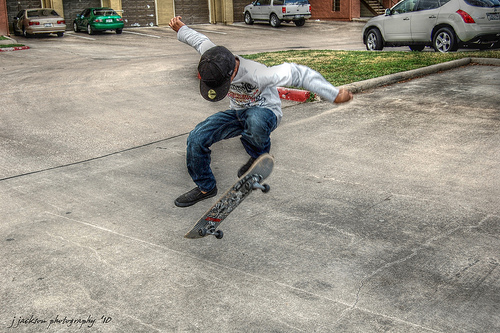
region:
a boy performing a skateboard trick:
[146, 16, 348, 260]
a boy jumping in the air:
[156, 36, 321, 268]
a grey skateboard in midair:
[183, 158, 277, 255]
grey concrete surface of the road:
[310, 188, 416, 265]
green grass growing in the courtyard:
[326, 53, 367, 71]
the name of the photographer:
[2, 311, 124, 331]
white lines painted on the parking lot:
[137, 29, 162, 42]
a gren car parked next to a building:
[73, 5, 145, 35]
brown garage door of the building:
[133, 0, 156, 23]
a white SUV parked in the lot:
[354, 2, 497, 53]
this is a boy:
[130, 32, 310, 210]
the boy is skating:
[151, 44, 311, 209]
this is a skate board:
[205, 170, 270, 237]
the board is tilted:
[204, 171, 258, 230]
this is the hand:
[285, 51, 352, 110]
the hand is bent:
[283, 61, 345, 109]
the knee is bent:
[242, 109, 277, 141]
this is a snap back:
[200, 52, 233, 94]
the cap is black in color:
[198, 52, 225, 78]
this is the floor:
[293, 217, 385, 327]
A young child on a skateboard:
[170, 21, 352, 235]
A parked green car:
[72, 5, 125, 33]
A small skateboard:
[183, 155, 274, 240]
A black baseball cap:
[195, 45, 236, 100]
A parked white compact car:
[360, 0, 499, 53]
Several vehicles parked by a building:
[0, 1, 310, 37]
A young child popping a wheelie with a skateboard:
[167, 19, 351, 237]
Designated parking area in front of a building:
[6, 18, 368, 43]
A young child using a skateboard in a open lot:
[172, 20, 353, 237]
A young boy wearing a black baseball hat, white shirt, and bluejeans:
[170, 15, 353, 207]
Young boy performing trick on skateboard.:
[168, 15, 354, 239]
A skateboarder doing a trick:
[167, 12, 352, 237]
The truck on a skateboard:
[199, 222, 224, 238]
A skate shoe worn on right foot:
[175, 185, 217, 204]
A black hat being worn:
[195, 44, 234, 101]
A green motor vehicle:
[72, 6, 122, 33]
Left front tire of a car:
[362, 26, 383, 48]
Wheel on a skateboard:
[261, 182, 270, 191]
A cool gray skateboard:
[185, 153, 272, 240]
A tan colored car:
[13, 8, 65, 33]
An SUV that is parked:
[243, 0, 309, 27]